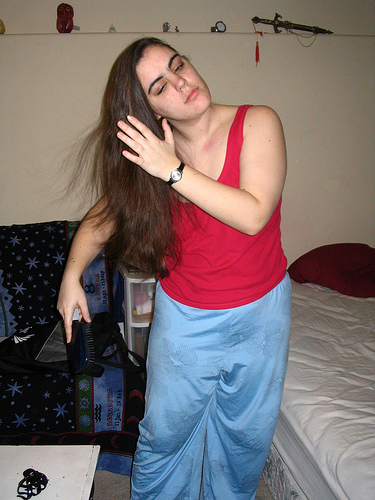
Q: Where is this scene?
A: The bedroom.